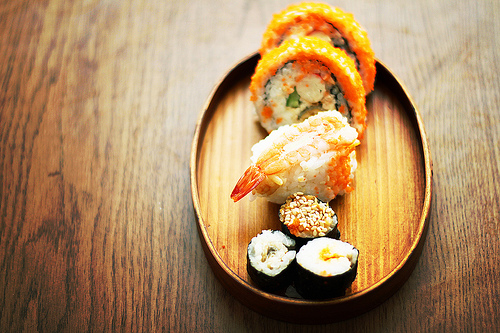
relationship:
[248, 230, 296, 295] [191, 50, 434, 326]
sushi on plate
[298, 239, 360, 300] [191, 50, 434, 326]
sushi on plate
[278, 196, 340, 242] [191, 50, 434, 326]
sushi on plate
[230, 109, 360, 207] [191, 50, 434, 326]
sushi on plate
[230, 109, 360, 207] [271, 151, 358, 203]
sushi has rice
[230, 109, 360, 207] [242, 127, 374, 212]
sushi in middle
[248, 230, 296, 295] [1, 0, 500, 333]
sushi on table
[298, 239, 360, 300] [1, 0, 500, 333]
sushi on table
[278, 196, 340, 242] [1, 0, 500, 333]
sushi on table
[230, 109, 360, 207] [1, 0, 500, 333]
sushi on table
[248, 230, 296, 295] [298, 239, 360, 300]
sushi near sushi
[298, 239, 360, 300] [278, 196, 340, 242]
sushi near sushi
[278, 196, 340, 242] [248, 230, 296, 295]
sushi near sushi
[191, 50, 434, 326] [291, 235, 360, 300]
plate holding sushi